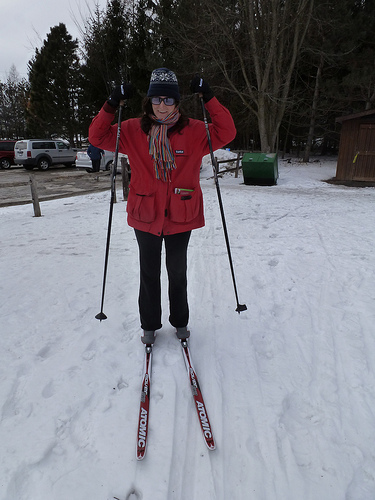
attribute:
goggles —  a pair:
[151, 97, 174, 106]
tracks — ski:
[217, 361, 266, 407]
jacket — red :
[80, 84, 238, 230]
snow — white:
[0, 148, 373, 498]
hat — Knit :
[143, 67, 188, 95]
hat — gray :
[148, 66, 180, 97]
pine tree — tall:
[21, 15, 83, 132]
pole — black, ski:
[186, 108, 298, 352]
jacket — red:
[87, 95, 237, 236]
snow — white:
[213, 202, 322, 448]